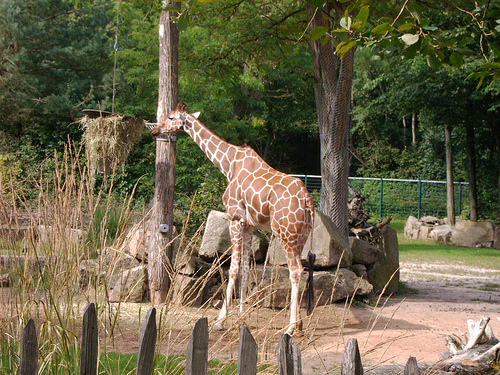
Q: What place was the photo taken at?
A: It was taken at the zoo.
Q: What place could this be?
A: It is a zoo.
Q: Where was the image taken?
A: It was taken at the zoo.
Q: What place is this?
A: It is a zoo.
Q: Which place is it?
A: It is a zoo.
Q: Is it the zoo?
A: Yes, it is the zoo.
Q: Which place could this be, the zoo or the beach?
A: It is the zoo.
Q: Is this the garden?
A: No, it is the zoo.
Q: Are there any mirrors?
A: No, there are no mirrors.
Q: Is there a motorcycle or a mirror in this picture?
A: No, there are no mirrors or motorcycles.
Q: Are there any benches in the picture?
A: No, there are no benches.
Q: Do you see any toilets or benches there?
A: No, there are no benches or toilets.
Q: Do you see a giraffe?
A: Yes, there is a giraffe.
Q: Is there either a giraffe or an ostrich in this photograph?
A: Yes, there is a giraffe.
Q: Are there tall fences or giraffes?
A: Yes, there is a tall giraffe.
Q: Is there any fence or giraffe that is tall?
A: Yes, the giraffe is tall.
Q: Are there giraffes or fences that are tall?
A: Yes, the giraffe is tall.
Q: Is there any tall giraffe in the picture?
A: Yes, there is a tall giraffe.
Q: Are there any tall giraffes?
A: Yes, there is a tall giraffe.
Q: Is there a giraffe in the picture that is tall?
A: Yes, there is a giraffe that is tall.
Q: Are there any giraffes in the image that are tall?
A: Yes, there is a giraffe that is tall.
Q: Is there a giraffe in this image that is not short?
A: Yes, there is a tall giraffe.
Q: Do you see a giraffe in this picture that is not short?
A: Yes, there is a tall giraffe.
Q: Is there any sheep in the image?
A: No, there is no sheep.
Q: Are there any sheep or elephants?
A: No, there are no sheep or elephants.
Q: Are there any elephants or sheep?
A: No, there are no sheep or elephants.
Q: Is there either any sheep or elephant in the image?
A: No, there are no sheep or elephants.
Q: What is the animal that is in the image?
A: The animal is a giraffe.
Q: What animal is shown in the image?
A: The animal is a giraffe.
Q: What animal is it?
A: The animal is a giraffe.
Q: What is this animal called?
A: This is a giraffe.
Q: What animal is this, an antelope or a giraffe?
A: This is a giraffe.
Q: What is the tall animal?
A: The animal is a giraffe.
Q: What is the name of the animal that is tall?
A: The animal is a giraffe.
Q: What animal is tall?
A: The animal is a giraffe.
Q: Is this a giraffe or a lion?
A: This is a giraffe.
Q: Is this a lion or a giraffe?
A: This is a giraffe.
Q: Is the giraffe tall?
A: Yes, the giraffe is tall.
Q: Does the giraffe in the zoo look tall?
A: Yes, the giraffe is tall.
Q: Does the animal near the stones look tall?
A: Yes, the giraffe is tall.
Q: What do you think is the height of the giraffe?
A: The giraffe is tall.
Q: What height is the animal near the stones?
A: The giraffe is tall.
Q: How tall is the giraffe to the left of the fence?
A: The giraffe is tall.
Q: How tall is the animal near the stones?
A: The giraffe is tall.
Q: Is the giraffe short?
A: No, the giraffe is tall.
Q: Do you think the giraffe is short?
A: No, the giraffe is tall.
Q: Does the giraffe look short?
A: No, the giraffe is tall.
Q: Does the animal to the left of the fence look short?
A: No, the giraffe is tall.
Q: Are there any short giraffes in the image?
A: No, there is a giraffe but it is tall.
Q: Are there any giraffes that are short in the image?
A: No, there is a giraffe but it is tall.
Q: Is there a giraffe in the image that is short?
A: No, there is a giraffe but it is tall.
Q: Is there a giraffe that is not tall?
A: No, there is a giraffe but it is tall.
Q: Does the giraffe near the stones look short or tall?
A: The giraffe is tall.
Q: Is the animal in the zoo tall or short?
A: The giraffe is tall.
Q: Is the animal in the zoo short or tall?
A: The giraffe is tall.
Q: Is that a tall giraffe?
A: Yes, that is a tall giraffe.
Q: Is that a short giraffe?
A: No, that is a tall giraffe.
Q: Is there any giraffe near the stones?
A: Yes, there is a giraffe near the stones.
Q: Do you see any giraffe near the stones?
A: Yes, there is a giraffe near the stones.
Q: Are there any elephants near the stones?
A: No, there is a giraffe near the stones.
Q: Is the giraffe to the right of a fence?
A: No, the giraffe is to the left of a fence.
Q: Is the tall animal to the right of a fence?
A: No, the giraffe is to the left of a fence.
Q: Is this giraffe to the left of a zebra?
A: No, the giraffe is to the left of the fence.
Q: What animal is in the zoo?
A: The giraffe is in the zoo.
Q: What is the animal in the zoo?
A: The animal is a giraffe.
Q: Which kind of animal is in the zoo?
A: The animal is a giraffe.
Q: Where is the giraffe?
A: The giraffe is in the zoo.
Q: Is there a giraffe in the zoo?
A: Yes, there is a giraffe in the zoo.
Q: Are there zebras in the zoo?
A: No, there is a giraffe in the zoo.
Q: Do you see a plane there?
A: No, there are no airplanes.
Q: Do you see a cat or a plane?
A: No, there are no airplanes or cats.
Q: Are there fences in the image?
A: Yes, there is a fence.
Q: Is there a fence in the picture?
A: Yes, there is a fence.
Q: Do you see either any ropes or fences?
A: Yes, there is a fence.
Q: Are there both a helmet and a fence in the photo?
A: No, there is a fence but no helmets.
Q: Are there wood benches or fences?
A: Yes, there is a wood fence.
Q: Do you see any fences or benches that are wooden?
A: Yes, the fence is wooden.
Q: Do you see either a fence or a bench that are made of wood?
A: Yes, the fence is made of wood.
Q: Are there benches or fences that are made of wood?
A: Yes, the fence is made of wood.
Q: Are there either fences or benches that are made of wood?
A: Yes, the fence is made of wood.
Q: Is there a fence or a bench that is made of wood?
A: Yes, the fence is made of wood.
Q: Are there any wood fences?
A: Yes, there is a wood fence.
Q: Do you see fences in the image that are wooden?
A: Yes, there is a fence that is wooden.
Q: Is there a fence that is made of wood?
A: Yes, there is a fence that is made of wood.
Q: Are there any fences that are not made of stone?
A: Yes, there is a fence that is made of wood.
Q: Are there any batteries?
A: No, there are no batteries.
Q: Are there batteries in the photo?
A: No, there are no batteries.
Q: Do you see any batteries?
A: No, there are no batteries.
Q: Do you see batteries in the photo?
A: No, there are no batteries.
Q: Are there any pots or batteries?
A: No, there are no batteries or pots.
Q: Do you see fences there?
A: Yes, there is a fence.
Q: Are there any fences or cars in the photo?
A: Yes, there is a fence.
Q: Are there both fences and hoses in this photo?
A: No, there is a fence but no hoses.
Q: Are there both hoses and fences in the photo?
A: No, there is a fence but no hoses.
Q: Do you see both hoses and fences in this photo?
A: No, there is a fence but no hoses.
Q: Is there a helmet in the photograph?
A: No, there are no helmets.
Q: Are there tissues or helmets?
A: No, there are no helmets or tissues.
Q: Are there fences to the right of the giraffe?
A: Yes, there is a fence to the right of the giraffe.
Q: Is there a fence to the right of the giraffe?
A: Yes, there is a fence to the right of the giraffe.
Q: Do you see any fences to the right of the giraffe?
A: Yes, there is a fence to the right of the giraffe.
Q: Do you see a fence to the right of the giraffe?
A: Yes, there is a fence to the right of the giraffe.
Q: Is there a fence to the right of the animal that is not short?
A: Yes, there is a fence to the right of the giraffe.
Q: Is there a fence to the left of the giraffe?
A: No, the fence is to the right of the giraffe.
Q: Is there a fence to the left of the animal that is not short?
A: No, the fence is to the right of the giraffe.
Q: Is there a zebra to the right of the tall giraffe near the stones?
A: No, there is a fence to the right of the giraffe.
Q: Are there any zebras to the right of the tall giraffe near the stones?
A: No, there is a fence to the right of the giraffe.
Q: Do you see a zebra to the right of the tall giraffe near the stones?
A: No, there is a fence to the right of the giraffe.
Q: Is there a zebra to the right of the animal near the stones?
A: No, there is a fence to the right of the giraffe.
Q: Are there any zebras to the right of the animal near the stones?
A: No, there is a fence to the right of the giraffe.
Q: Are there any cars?
A: No, there are no cars.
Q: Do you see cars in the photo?
A: No, there are no cars.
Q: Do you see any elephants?
A: No, there are no elephants.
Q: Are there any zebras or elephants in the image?
A: No, there are no elephants or zebras.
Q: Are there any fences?
A: Yes, there is a fence.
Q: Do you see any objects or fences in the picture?
A: Yes, there is a fence.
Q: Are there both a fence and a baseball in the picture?
A: No, there is a fence but no baseballs.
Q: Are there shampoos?
A: No, there are no shampoos.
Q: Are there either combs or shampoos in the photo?
A: No, there are no shampoos or combs.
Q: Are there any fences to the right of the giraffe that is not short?
A: Yes, there is a fence to the right of the giraffe.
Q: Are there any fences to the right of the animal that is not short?
A: Yes, there is a fence to the right of the giraffe.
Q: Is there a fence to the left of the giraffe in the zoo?
A: No, the fence is to the right of the giraffe.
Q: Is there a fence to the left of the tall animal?
A: No, the fence is to the right of the giraffe.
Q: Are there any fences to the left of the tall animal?
A: No, the fence is to the right of the giraffe.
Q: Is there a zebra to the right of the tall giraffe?
A: No, there is a fence to the right of the giraffe.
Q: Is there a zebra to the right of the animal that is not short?
A: No, there is a fence to the right of the giraffe.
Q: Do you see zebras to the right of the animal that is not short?
A: No, there is a fence to the right of the giraffe.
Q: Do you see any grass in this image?
A: Yes, there is grass.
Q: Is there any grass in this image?
A: Yes, there is grass.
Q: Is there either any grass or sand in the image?
A: Yes, there is grass.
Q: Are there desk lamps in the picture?
A: No, there are no desk lamps.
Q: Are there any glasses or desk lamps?
A: No, there are no desk lamps or glasses.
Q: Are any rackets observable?
A: No, there are no rackets.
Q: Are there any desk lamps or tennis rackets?
A: No, there are no tennis rackets or desk lamps.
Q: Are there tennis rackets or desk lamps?
A: No, there are no tennis rackets or desk lamps.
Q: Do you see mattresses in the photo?
A: No, there are no mattresses.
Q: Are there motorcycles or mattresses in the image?
A: No, there are no mattresses or motorcycles.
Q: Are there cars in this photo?
A: No, there are no cars.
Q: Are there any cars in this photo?
A: No, there are no cars.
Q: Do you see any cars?
A: No, there are no cars.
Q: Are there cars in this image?
A: No, there are no cars.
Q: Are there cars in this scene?
A: No, there are no cars.